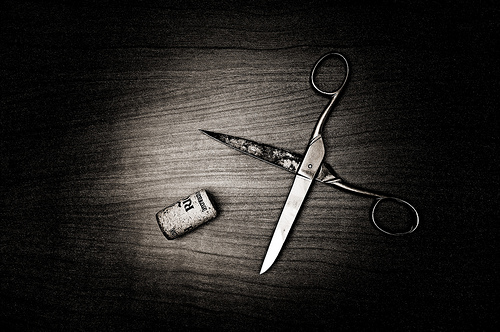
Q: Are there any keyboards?
A: No, there are no keyboards.